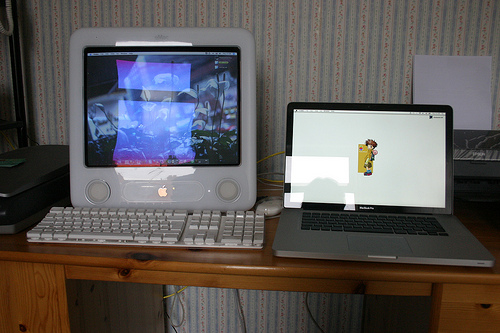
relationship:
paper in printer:
[417, 48, 493, 122] [421, 138, 493, 207]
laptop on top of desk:
[272, 102, 493, 269] [7, 236, 496, 332]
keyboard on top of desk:
[34, 203, 271, 260] [7, 236, 496, 332]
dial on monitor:
[217, 178, 250, 206] [86, 28, 247, 206]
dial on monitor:
[86, 181, 118, 204] [86, 28, 247, 206]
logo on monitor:
[156, 184, 169, 200] [86, 28, 247, 206]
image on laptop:
[355, 143, 384, 177] [272, 102, 493, 269]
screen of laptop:
[297, 119, 448, 208] [272, 102, 493, 269]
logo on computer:
[156, 184, 169, 200] [38, 32, 270, 258]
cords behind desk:
[136, 286, 266, 322] [7, 236, 496, 332]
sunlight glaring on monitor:
[136, 69, 197, 177] [86, 28, 247, 206]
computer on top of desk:
[38, 32, 270, 258] [7, 236, 496, 332]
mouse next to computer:
[257, 182, 288, 219] [38, 32, 270, 258]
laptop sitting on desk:
[272, 102, 493, 269] [7, 236, 496, 332]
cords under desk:
[136, 286, 266, 322] [7, 236, 496, 332]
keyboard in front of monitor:
[34, 203, 271, 260] [86, 28, 247, 206]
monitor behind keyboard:
[86, 28, 247, 206] [34, 203, 271, 260]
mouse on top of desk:
[257, 182, 288, 219] [7, 236, 496, 332]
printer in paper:
[421, 138, 493, 207] [417, 48, 493, 122]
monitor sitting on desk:
[86, 28, 247, 206] [7, 236, 496, 332]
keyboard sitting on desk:
[34, 203, 271, 260] [7, 236, 496, 332]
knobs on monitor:
[85, 176, 237, 204] [86, 28, 247, 206]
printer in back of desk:
[421, 138, 493, 207] [7, 236, 496, 332]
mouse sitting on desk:
[257, 182, 288, 219] [7, 236, 496, 332]